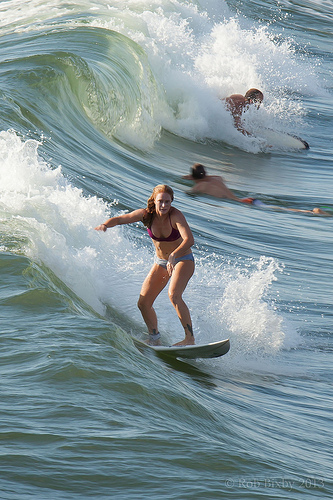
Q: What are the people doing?
A: Surfing.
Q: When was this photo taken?
A: Daytime.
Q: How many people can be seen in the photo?
A: Three.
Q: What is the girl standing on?
A: A surfboard.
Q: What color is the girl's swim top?
A: Purple.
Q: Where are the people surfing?
A: The ocean.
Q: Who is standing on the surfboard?
A: The girl.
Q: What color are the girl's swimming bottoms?
A: Blue.